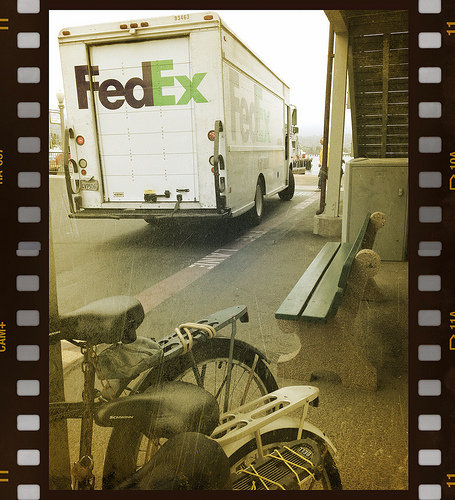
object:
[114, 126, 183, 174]
white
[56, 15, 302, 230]
truck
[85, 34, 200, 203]
door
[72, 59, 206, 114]
logo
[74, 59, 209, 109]
letters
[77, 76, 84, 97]
black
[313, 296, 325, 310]
green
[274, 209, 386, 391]
bench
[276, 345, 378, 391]
support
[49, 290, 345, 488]
bikes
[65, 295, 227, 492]
seats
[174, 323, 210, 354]
locks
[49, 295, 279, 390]
bike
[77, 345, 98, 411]
chain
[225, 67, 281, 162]
fedex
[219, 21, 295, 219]
side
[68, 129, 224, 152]
light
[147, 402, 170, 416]
black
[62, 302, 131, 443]
two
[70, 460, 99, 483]
lock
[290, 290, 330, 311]
wood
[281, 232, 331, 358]
vacant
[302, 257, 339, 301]
seat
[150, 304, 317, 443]
racks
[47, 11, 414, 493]
photo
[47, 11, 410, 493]
day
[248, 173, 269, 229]
tire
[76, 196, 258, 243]
rear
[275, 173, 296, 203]
tire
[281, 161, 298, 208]
right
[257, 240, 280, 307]
sidewalk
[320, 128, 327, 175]
man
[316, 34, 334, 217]
pole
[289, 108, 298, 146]
mirror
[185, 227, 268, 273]
firelane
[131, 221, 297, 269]
curb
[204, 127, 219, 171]
signal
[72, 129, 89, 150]
left signal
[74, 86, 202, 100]
multicolor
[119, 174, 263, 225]
back wheel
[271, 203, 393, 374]
public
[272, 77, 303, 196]
front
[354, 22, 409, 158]
back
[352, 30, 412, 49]
stairs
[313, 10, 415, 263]
building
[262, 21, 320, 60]
clouds